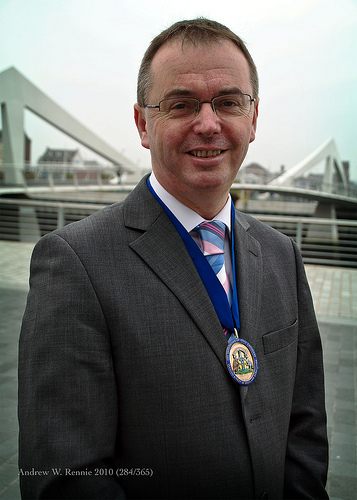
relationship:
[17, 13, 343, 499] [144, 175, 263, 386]
man wearing medal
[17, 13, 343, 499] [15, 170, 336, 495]
he dressed in suit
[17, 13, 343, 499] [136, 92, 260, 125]
man wearing glasses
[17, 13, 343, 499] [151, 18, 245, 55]
man has hair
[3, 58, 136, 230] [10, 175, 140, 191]
bridge in background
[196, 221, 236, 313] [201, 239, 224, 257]
tie has stripe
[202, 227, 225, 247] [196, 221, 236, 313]
stripe on tie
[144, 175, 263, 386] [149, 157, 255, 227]
ribbon around neck